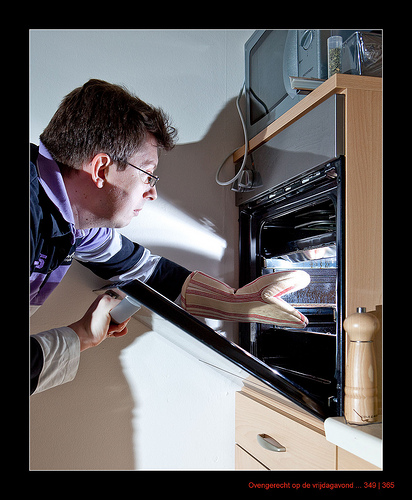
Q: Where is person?
A: At oven.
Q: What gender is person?
A: Man.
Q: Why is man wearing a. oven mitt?
A: Safety.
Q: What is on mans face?
A: Glasses.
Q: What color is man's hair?
A: Black.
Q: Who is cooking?
A: A male person.